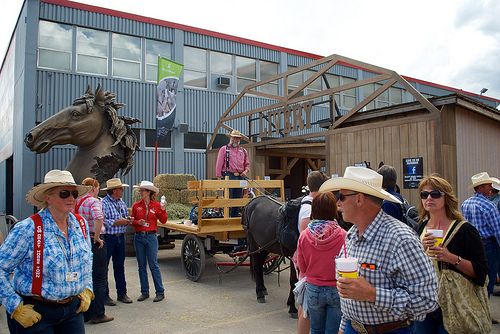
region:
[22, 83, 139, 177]
Bronze statue of horse's head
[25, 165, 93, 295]
Woman wearing red suspenders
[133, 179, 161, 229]
Woman wearing red shirt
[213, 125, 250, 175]
Man wearing black suspenders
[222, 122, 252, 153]
Man with gray hair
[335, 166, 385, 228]
Man wearing black sunglasses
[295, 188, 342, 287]
Girl wearing pink hoodie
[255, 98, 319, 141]
"Livery" spelled out in wood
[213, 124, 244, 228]
Man standing on a trailer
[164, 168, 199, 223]
Hay on a wagon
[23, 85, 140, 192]
Brown statue of a horse's head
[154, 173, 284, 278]
A wooden horsecart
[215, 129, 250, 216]
A tourist standing aboard a horsecart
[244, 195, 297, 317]
A real black horse drawing the cart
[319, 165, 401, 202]
A hat on a man's head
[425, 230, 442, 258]
A glass of soda in a woman's hand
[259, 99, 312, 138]
The word 'Livery' on a shade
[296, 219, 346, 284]
A pink hoodie a woman is wearing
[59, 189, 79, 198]
Sunglasses a man in blue is wearing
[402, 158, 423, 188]
A sign on a wall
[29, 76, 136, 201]
the head of a horse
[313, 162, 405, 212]
a white cowboy hat on top of man's head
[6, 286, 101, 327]
man wearing yellow gloves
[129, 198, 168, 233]
woman wearing a red shirt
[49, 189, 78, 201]
woman wearing dark sunglasses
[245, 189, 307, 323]
a horse in the back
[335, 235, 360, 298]
man is holding a drink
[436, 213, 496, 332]
woman is holding a bag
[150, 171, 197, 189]
a block of hay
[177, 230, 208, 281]
a wheel underneath the cart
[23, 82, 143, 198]
the statue of the horse's head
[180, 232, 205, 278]
the wheel on the trailer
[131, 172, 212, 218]
the hay bales on the trailer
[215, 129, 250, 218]
the man standing on the trailer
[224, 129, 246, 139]
the hat of the man standing on the trailer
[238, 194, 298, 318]
the horse in front of the trailer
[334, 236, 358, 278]
the cup in the man's hand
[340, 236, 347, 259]
the straw in the man's cup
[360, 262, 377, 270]
the object in the man's shirt pocket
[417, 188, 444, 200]
the sunglasses on the woman's face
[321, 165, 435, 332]
Man wearing a plaid shirt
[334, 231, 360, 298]
Cup in man's hand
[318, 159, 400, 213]
Cowboy hat on man's head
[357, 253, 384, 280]
Cellphone in man's pocket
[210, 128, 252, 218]
Man wearing a red shirt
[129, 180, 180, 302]
Woman wearing a red shirt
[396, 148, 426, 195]
Black sign on door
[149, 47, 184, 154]
Sign hanging on a pole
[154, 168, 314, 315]
Black horse pulling a wagon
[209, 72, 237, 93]
Air conditioning unit in window